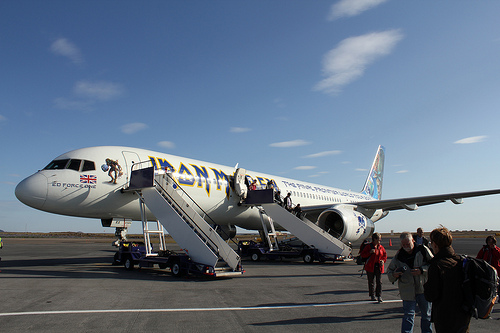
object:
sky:
[0, 0, 500, 232]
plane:
[14, 140, 500, 252]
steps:
[213, 266, 234, 273]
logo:
[101, 155, 126, 186]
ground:
[0, 235, 500, 333]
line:
[112, 306, 135, 319]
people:
[421, 222, 496, 333]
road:
[0, 257, 500, 333]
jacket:
[362, 243, 387, 274]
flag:
[78, 173, 98, 183]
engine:
[316, 207, 377, 243]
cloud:
[308, 27, 410, 98]